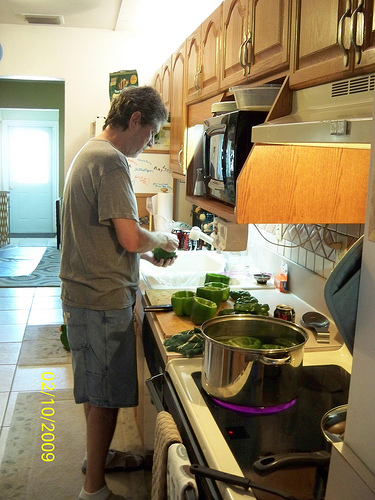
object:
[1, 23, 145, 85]
wall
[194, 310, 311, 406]
pot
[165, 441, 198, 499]
towels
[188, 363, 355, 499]
stove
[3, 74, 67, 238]
door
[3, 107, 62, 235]
door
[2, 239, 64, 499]
floor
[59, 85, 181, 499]
man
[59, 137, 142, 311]
tee shirt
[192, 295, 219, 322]
peppers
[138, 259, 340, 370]
counter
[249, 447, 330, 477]
handle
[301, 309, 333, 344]
spoon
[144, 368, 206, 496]
handle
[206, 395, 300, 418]
lit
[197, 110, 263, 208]
microwave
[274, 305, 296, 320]
soda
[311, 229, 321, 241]
tile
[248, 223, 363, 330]
wall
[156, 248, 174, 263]
bell pepper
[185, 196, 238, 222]
shelf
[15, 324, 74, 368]
rug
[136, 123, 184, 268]
down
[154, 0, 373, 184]
cabinets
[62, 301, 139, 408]
shorts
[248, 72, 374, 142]
hood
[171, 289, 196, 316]
bell peppers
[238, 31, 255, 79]
handles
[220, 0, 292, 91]
cabinet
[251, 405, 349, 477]
frying pan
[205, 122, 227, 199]
black door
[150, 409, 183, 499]
towel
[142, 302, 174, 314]
knife